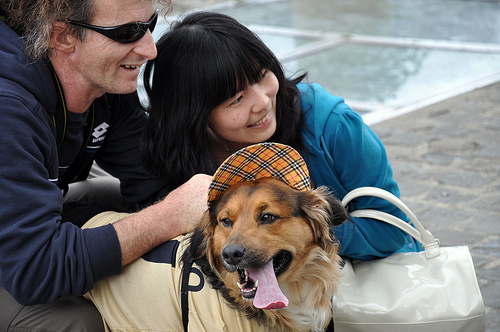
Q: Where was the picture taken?
A: On a sidewalk.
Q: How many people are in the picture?
A: Two.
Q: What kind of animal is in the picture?
A: A dog.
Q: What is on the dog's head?
A: A hat.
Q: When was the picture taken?
A: Daytime.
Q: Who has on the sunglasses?
A: The man.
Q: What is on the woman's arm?
A: A purse.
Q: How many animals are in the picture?
A: One.